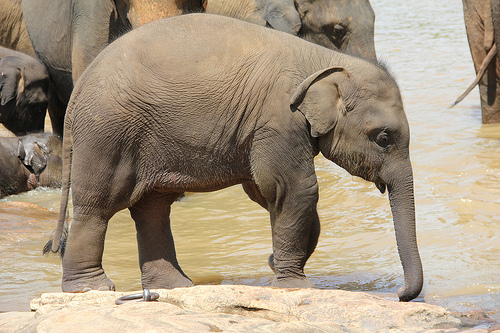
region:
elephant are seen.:
[34, 17, 444, 284]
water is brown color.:
[203, 212, 248, 262]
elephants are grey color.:
[136, 72, 272, 142]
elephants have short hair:
[337, 42, 399, 87]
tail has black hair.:
[43, 225, 78, 263]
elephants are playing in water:
[16, 96, 446, 315]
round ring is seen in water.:
[118, 278, 170, 317]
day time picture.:
[26, 76, 450, 305]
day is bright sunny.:
[41, 41, 443, 310]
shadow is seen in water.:
[78, 241, 332, 331]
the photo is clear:
[4, 2, 499, 322]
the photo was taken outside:
[1, 0, 499, 327]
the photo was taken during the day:
[7, 3, 498, 331]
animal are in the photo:
[31, 25, 445, 315]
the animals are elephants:
[4, 4, 493, 319]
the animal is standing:
[30, 55, 443, 302]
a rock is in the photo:
[10, 292, 440, 332]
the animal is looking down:
[351, 80, 497, 323]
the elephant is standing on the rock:
[46, 17, 463, 332]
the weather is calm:
[10, 4, 497, 329]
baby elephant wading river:
[23, 22, 470, 304]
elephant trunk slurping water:
[367, 160, 447, 320]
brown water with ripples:
[437, 169, 478, 286]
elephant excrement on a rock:
[102, 286, 185, 310]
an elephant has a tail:
[446, 37, 497, 124]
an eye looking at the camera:
[369, 106, 411, 166]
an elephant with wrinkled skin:
[121, 75, 283, 197]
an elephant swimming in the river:
[1, 121, 64, 203]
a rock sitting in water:
[248, 297, 425, 327]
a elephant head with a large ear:
[285, 61, 422, 191]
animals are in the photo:
[10, 1, 481, 316]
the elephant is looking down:
[338, 95, 473, 223]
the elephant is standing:
[39, 27, 413, 321]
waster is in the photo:
[423, 120, 495, 298]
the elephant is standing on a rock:
[16, 16, 460, 329]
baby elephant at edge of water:
[42, 13, 456, 314]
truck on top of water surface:
[322, 56, 452, 309]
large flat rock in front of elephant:
[28, 273, 469, 326]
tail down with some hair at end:
[39, 98, 81, 269]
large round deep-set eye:
[368, 121, 396, 153]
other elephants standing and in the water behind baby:
[5, 8, 430, 212]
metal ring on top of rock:
[87, 275, 179, 309]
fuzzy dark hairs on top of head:
[336, 32, 419, 113]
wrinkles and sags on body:
[108, 58, 277, 192]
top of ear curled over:
[281, 58, 367, 144]